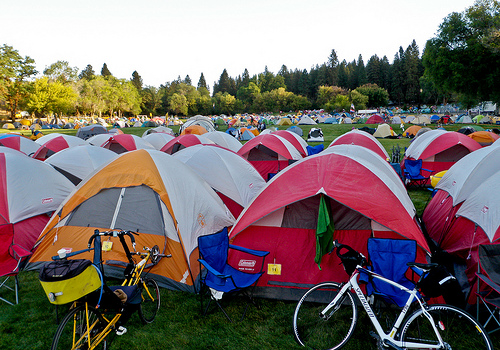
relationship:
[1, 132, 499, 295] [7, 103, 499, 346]
tents are in field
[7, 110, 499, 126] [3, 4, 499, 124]
tents in distance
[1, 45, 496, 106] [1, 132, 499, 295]
trees are beyond tents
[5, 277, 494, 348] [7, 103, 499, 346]
grass on ground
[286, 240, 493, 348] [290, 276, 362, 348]
bicycle has wheel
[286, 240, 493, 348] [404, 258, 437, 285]
bicycle has seat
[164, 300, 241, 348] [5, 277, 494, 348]
patch of grass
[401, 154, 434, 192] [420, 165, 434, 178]
chair that has an arm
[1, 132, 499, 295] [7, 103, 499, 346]
tents in a field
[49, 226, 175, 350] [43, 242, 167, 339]
reclining bicycle that yellow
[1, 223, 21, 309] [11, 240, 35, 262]
folding chair has black trim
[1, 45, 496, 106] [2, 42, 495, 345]
trees are in park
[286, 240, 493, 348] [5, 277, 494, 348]
bicycle on grass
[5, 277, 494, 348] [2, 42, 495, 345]
grass in park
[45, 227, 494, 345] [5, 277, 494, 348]
bicycles are on grass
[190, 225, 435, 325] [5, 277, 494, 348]
two folding chairs are on grass